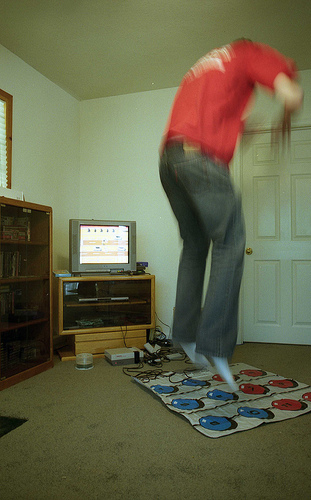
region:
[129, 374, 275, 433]
Blue circles on pad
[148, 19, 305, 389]
Man who is jumping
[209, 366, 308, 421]
Red buttons on pad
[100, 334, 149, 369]
Video game console under tv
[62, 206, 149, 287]
Tv on cabinet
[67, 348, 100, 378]
Holder of cds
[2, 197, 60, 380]
Bookcase next to tv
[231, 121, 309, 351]
Door next to television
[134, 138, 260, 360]
blue jeans on jumping man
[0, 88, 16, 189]
window above the bookcase with blinds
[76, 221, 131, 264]
an illuminated television screen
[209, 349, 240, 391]
a white sock on the man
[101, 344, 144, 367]
an original Nintendo console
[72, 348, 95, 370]
a spindle of CDs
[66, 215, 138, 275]
a gray television set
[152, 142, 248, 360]
a pair of blue jeans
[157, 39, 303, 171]
a red tee shirt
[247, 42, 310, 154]
the arm of a man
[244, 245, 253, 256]
a golden door knob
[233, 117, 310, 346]
a white door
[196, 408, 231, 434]
a blue ball drawing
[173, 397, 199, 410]
a blue ball drawing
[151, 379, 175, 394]
a blue ball drawing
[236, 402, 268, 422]
a blue ball drawing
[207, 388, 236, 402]
a blue ball drawing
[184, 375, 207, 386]
a blue ball drawing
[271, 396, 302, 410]
a red ball drawing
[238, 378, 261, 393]
a red ball drawing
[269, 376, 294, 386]
a red ball drawing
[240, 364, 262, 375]
a red ball drawing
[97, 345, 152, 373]
Nintendo video game console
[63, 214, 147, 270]
Television set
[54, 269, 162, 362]
Wood tv stand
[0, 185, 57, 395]
Wood media center with glass doors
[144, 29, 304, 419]
Person in a red shirt jumping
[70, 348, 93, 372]
Case of cds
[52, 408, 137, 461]
Carpet on the floor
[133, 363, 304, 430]
Game pad for Nintendo game system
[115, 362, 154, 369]
Cords for video game system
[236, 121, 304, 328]
White door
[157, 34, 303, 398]
a man playing a video game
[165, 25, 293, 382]
a man jumps in the air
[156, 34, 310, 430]
a man jumping on a mat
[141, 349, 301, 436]
the game mat has red and blue dots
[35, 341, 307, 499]
the carpet is beige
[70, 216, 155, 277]
a television set on a stand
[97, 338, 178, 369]
a game council is on the floor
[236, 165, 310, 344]
the door is white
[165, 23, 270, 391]
the man is wearing jeans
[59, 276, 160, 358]
a wood television stand